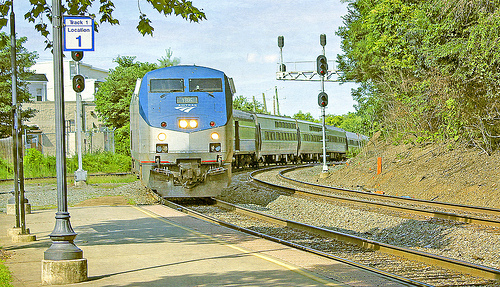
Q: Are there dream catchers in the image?
A: No, there are no dream catchers.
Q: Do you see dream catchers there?
A: No, there are no dream catchers.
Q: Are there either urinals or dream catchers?
A: No, there are no dream catchers or urinals.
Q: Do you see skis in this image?
A: No, there are no skis.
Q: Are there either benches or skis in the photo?
A: No, there are no skis or benches.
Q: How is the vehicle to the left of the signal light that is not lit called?
A: The vehicle is a locomotive.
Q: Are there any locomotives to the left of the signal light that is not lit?
A: Yes, there is a locomotive to the left of the traffic light.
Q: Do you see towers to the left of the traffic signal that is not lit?
A: No, there is a locomotive to the left of the traffic signal.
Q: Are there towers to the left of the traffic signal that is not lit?
A: No, there is a locomotive to the left of the traffic signal.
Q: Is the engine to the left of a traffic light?
A: Yes, the engine is to the left of a traffic light.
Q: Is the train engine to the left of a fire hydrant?
A: No, the train engine is to the left of a traffic light.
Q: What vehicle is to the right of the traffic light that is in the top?
A: The vehicle is a locomotive.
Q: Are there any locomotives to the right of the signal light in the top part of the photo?
A: Yes, there is a locomotive to the right of the traffic signal.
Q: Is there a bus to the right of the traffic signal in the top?
A: No, there is a locomotive to the right of the traffic light.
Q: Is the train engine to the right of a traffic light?
A: Yes, the train engine is to the right of a traffic light.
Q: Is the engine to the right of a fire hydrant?
A: No, the engine is to the right of a traffic light.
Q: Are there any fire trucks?
A: No, there are no fire trucks.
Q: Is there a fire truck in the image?
A: No, there are no fire trucks.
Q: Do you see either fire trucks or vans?
A: No, there are no fire trucks or vans.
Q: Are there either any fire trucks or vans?
A: No, there are no fire trucks or vans.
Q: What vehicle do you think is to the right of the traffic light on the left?
A: The vehicle is a car.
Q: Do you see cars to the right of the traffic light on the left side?
A: Yes, there is a car to the right of the traffic light.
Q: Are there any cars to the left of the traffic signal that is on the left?
A: No, the car is to the right of the traffic signal.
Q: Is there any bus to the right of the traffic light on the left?
A: No, there is a car to the right of the traffic light.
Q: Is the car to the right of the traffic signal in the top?
A: Yes, the car is to the right of the traffic signal.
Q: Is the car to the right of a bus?
A: No, the car is to the right of the traffic signal.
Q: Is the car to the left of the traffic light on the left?
A: No, the car is to the right of the traffic signal.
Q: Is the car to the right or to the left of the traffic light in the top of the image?
A: The car is to the right of the traffic signal.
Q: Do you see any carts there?
A: No, there are no carts.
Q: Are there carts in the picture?
A: No, there are no carts.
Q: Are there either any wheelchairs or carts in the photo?
A: No, there are no carts or wheelchairs.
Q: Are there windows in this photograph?
A: Yes, there is a window.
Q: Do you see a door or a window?
A: Yes, there is a window.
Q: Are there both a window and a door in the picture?
A: No, there is a window but no doors.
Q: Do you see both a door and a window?
A: No, there is a window but no doors.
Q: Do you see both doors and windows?
A: No, there is a window but no doors.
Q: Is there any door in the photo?
A: No, there are no doors.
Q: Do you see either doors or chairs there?
A: No, there are no doors or chairs.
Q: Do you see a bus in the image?
A: No, there are no buses.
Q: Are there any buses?
A: No, there are no buses.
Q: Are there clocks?
A: No, there are no clocks.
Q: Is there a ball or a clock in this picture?
A: No, there are no clocks or balls.